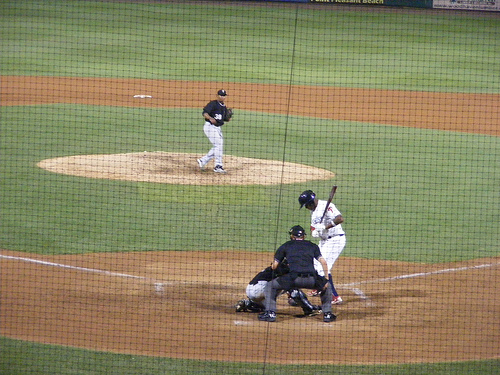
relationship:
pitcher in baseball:
[193, 82, 244, 176] [0, 4, 493, 365]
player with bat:
[298, 187, 360, 308] [315, 182, 341, 232]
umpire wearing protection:
[264, 222, 339, 331] [280, 240, 325, 286]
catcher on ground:
[236, 254, 281, 314] [50, 173, 168, 286]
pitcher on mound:
[193, 82, 244, 176] [36, 143, 334, 197]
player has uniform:
[298, 187, 360, 308] [309, 201, 345, 267]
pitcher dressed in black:
[193, 82, 244, 176] [202, 103, 225, 122]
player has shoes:
[298, 187, 360, 308] [323, 289, 342, 308]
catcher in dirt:
[236, 254, 281, 314] [165, 265, 232, 352]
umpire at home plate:
[264, 222, 339, 331] [286, 297, 311, 319]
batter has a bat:
[298, 187, 360, 308] [315, 182, 341, 232]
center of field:
[5, 89, 470, 205] [0, 4, 493, 365]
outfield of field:
[4, 1, 486, 75] [1, 3, 500, 142]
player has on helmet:
[298, 187, 360, 308] [292, 188, 320, 203]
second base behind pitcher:
[121, 80, 172, 112] [193, 82, 244, 176]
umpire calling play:
[264, 222, 339, 331] [165, 85, 373, 344]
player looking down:
[298, 187, 360, 308] [265, 246, 278, 258]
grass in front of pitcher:
[180, 179, 287, 246] [193, 82, 244, 176]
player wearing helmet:
[298, 187, 360, 308] [292, 188, 320, 203]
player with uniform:
[298, 187, 360, 308] [309, 201, 345, 267]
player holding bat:
[298, 187, 360, 308] [315, 182, 341, 232]